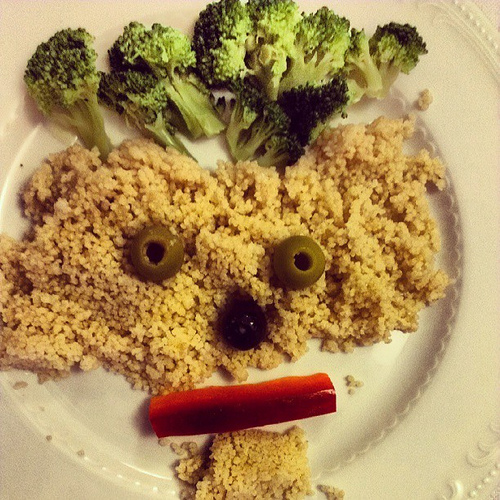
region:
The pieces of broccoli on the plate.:
[15, 8, 432, 158]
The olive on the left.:
[125, 223, 190, 286]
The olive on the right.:
[272, 234, 329, 281]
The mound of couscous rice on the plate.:
[26, 145, 441, 387]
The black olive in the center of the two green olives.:
[219, 285, 261, 350]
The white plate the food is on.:
[7, 6, 484, 498]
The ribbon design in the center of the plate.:
[382, 100, 462, 451]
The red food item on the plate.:
[139, 384, 346, 430]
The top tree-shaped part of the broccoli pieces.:
[12, 6, 424, 99]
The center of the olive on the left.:
[146, 240, 165, 262]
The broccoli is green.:
[16, 51, 356, 150]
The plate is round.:
[26, 163, 478, 478]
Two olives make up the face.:
[118, 220, 350, 293]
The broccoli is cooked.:
[41, 57, 298, 144]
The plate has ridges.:
[383, 376, 483, 492]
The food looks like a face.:
[68, 195, 368, 439]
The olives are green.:
[112, 222, 352, 286]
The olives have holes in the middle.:
[111, 190, 349, 315]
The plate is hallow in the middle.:
[23, 79, 473, 487]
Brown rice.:
[62, 154, 384, 209]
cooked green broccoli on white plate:
[20, 31, 117, 161]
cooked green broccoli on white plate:
[111, 7, 230, 144]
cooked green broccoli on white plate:
[181, 10, 428, 116]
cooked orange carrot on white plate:
[122, 386, 355, 439]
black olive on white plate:
[215, 296, 277, 353]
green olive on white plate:
[121, 220, 178, 282]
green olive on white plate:
[271, 230, 328, 290]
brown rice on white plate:
[325, 140, 445, 330]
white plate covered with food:
[340, 360, 475, 490]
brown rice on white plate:
[31, 180, 122, 401]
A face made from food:
[14, 95, 453, 407]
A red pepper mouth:
[125, 359, 346, 430]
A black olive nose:
[204, 287, 273, 352]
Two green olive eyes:
[110, 211, 346, 281]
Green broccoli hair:
[50, 25, 426, 156]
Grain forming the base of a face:
[29, 148, 429, 383]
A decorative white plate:
[361, 354, 487, 483]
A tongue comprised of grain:
[198, 426, 316, 493]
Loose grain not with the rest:
[342, 370, 365, 396]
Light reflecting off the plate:
[371, 321, 407, 364]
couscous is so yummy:
[32, 226, 105, 301]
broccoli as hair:
[58, 41, 290, 129]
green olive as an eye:
[110, 222, 200, 298]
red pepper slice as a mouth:
[141, 365, 356, 443]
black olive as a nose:
[215, 295, 277, 362]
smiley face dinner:
[22, 26, 417, 497]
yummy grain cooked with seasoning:
[41, 211, 114, 316]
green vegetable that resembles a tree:
[56, 48, 376, 123]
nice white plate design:
[430, 6, 496, 86]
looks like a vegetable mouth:
[127, 367, 374, 447]